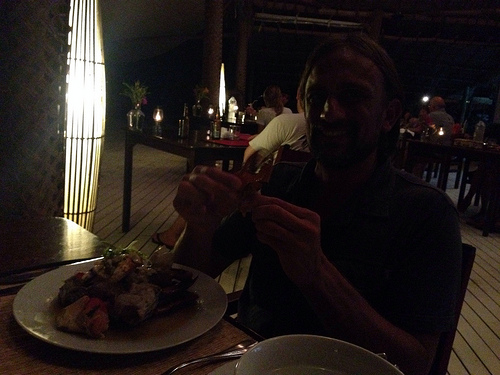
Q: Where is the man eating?
A: Restaurant.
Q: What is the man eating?
A: Food.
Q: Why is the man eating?
A: Hungry.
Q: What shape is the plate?
A: Circle.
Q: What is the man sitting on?
A: Chair.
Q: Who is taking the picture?
A: Man's companion.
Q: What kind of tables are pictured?
A: Wooden.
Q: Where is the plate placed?
A: Table.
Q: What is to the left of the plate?
A: A light.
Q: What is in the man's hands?
A: It's food.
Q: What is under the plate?
A: A table.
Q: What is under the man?
A: A carpet.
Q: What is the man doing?
A: Eating food.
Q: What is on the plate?
A: It's meat.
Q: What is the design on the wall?
A: It's lattice.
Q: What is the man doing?
A: Smiling for the camera.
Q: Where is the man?
A: At a restaurant.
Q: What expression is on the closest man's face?
A: Smile.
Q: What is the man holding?
A: A crab.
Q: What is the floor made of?
A: Wood.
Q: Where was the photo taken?
A: Restaurant.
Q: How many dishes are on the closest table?
A: 2.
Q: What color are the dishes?
A: White.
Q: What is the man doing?
A: Eating.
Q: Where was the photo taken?
A: Restaurant.